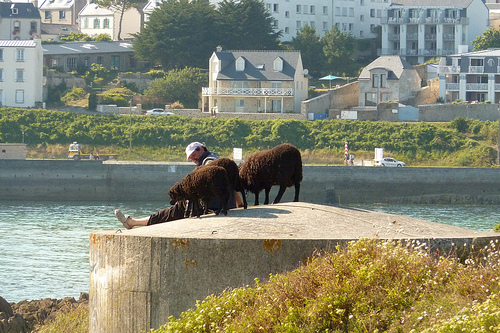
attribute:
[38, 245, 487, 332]
grass — green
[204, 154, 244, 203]
sheep — brown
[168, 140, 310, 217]
sheep — three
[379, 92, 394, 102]
window — glass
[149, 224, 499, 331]
grass — green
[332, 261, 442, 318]
grass — green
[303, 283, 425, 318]
grass — green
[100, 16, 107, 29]
window — glass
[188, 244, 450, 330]
grass — green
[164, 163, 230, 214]
sheep — Brown 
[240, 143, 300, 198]
sheep — Brown 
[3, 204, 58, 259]
water — blue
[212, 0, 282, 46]
trees — large, green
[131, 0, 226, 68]
trees — large, green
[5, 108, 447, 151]
bushes — green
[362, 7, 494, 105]
building — large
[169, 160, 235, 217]
sheep — brown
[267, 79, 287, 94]
window — glass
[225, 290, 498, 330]
grass — green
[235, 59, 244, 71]
window — glass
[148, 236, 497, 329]
grass — green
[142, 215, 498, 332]
grass — green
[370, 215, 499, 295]
flowers — white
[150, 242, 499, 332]
grass — green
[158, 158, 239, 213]
sheep — brown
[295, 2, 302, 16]
window — glass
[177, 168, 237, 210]
fur — brown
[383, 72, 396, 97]
window — glass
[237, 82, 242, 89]
window — glass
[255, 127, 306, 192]
sheep — brown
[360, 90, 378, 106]
window — glass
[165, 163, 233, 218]
sheep — brown, chocolate brown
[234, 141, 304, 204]
sheep — brown, chocolate brown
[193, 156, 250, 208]
sheep — chocolate brown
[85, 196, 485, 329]
pier — cement